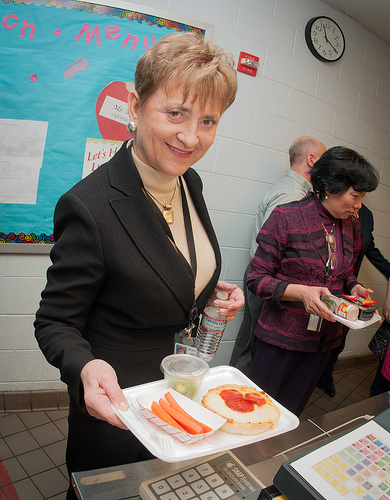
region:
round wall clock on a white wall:
[293, 11, 356, 67]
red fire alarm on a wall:
[234, 39, 267, 80]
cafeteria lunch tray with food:
[108, 348, 304, 469]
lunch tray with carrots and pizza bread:
[103, 359, 317, 467]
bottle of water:
[199, 273, 227, 368]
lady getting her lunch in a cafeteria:
[291, 149, 377, 413]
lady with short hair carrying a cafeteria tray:
[108, 24, 289, 495]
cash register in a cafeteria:
[127, 464, 310, 495]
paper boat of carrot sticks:
[131, 391, 225, 442]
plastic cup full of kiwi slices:
[161, 358, 212, 394]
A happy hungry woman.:
[120, 24, 222, 175]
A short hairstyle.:
[147, 21, 241, 98]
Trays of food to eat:
[93, 277, 387, 452]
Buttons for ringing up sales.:
[129, 417, 383, 496]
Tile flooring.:
[2, 356, 388, 431]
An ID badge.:
[294, 298, 321, 333]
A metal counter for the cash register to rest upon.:
[62, 400, 387, 479]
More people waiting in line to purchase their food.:
[276, 136, 388, 384]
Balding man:
[278, 123, 324, 169]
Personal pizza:
[201, 386, 273, 430]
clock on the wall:
[305, 13, 366, 67]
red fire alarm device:
[237, 44, 264, 80]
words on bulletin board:
[2, 16, 133, 76]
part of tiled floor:
[6, 415, 58, 470]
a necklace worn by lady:
[318, 219, 336, 271]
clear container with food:
[160, 353, 203, 392]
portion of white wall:
[303, 82, 378, 126]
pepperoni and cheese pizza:
[210, 388, 270, 434]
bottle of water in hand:
[195, 274, 237, 350]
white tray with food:
[111, 365, 296, 448]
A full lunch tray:
[90, 347, 320, 439]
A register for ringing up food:
[266, 401, 380, 489]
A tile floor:
[5, 417, 64, 482]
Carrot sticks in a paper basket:
[137, 393, 231, 437]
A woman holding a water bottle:
[182, 263, 248, 375]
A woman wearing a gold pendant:
[147, 166, 190, 245]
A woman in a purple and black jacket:
[253, 188, 364, 356]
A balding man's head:
[272, 119, 337, 183]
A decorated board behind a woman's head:
[1, 14, 220, 178]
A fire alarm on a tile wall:
[232, 45, 276, 79]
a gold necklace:
[142, 187, 184, 224]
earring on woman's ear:
[122, 90, 140, 132]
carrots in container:
[140, 392, 206, 438]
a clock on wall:
[303, 11, 354, 74]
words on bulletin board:
[71, 5, 138, 61]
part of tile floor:
[2, 423, 68, 460]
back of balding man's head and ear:
[289, 135, 315, 166]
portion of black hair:
[323, 156, 371, 182]